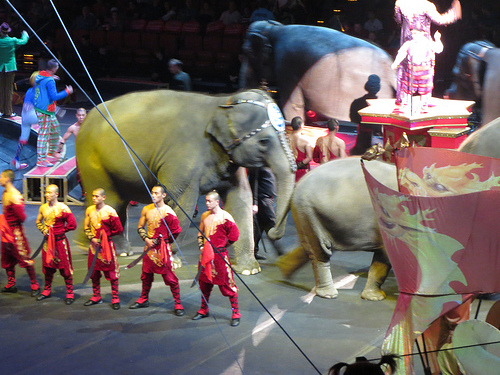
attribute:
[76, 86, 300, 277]
elephant — grey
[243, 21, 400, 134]
elephant — grey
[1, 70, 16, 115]
pants — green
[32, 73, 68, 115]
jacket — blue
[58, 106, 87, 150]
man — shirtless, bald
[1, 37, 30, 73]
jacket — green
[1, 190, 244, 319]
uniform — red